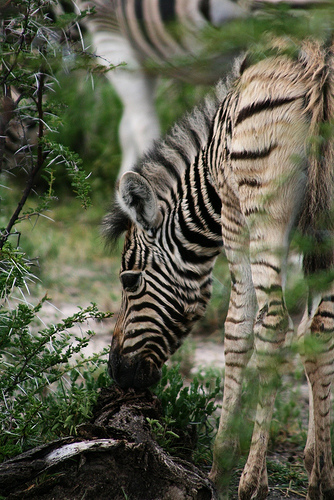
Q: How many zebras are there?
A: One.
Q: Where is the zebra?
A: By a bush.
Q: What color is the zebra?
A: Black and white.